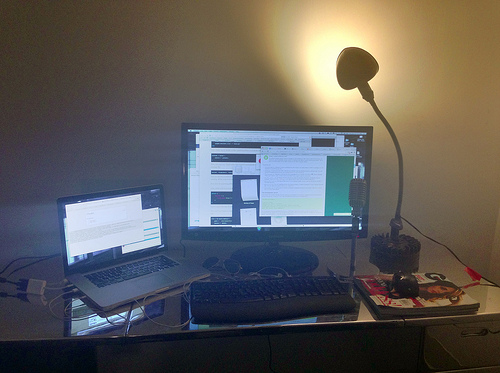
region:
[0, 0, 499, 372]
the interior of a room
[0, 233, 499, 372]
a mirrored desk against the wall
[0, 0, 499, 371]
a white wall in the background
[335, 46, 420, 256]
a black desk lamp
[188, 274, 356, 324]
a black computer keyboard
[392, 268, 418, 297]
a black computer mouse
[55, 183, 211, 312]
a laptop computer on the desk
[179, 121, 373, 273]
a computer monitor on the desk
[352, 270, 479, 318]
a small stack of magazines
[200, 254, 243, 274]
a pair of sunglasses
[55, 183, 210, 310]
An open laptop with a screen display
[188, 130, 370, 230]
Screen of a big monitor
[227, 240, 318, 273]
Base of the moniter screen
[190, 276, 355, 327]
A black keyboard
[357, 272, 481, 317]
Magazines under the mouse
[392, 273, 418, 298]
A mouse kept on a magazine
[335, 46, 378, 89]
An electric lamp facing the wall behind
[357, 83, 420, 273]
The base and arm of the lamp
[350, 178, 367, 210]
A microphone on a stand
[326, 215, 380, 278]
Microphone stand and base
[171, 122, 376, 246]
a computer monitor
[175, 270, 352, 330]
a computer keyboard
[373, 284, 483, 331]
a stack of magazines on a desk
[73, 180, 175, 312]
a laptop computer on a desk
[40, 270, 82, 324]
several cords plugged into a laptop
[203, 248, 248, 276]
a pair of sunglasses on a desk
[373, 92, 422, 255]
a tall desk lamp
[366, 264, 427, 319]
a black computer mouse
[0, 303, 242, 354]
a glass top desk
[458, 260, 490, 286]
a red tag on a cord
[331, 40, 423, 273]
desk lamp facing wall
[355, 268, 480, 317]
magazine under computer mouse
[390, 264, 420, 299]
black computer mouse on magazine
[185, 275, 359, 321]
black computer keyboard on desk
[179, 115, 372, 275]
large computer monitor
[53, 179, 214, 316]
small silver laptop on desk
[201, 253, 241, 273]
fashion sunglasses on desk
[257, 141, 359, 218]
one panel opened on monitor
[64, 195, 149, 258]
panel opened on laptop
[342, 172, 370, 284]
pc microphone on desk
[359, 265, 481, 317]
a pile of magazines on the desk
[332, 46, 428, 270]
a lamp turned on towards the wall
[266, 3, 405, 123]
light reflecting on the wall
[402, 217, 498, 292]
black cord of the lamp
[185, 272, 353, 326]
black computer keyboard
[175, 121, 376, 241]
a black computer screen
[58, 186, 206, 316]
a silver and black laptop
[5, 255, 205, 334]
cords on the table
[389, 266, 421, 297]
a mouse on the magazines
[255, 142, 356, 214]
a window open on the screen